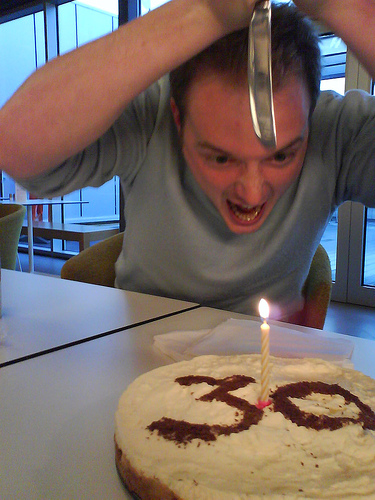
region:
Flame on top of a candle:
[251, 296, 273, 322]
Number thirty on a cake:
[147, 373, 374, 438]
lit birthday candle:
[252, 298, 275, 407]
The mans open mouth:
[225, 202, 270, 227]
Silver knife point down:
[242, 1, 283, 150]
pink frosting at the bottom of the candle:
[255, 397, 272, 410]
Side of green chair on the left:
[0, 192, 25, 269]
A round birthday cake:
[114, 352, 373, 497]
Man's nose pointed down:
[235, 170, 270, 206]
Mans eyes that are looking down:
[197, 135, 316, 167]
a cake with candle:
[91, 266, 371, 479]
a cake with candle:
[124, 270, 356, 486]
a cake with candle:
[146, 265, 353, 499]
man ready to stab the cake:
[78, 1, 365, 491]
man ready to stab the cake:
[106, 5, 373, 481]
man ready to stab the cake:
[119, 2, 362, 472]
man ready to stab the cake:
[115, 7, 368, 470]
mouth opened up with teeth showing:
[215, 192, 269, 226]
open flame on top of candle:
[251, 293, 273, 325]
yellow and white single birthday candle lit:
[254, 297, 275, 404]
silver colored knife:
[241, 0, 286, 155]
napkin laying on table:
[147, 312, 359, 367]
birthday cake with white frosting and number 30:
[107, 295, 374, 498]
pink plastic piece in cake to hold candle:
[250, 396, 276, 413]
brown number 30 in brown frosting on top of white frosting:
[143, 365, 373, 452]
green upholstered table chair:
[58, 223, 337, 330]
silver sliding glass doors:
[300, 15, 374, 314]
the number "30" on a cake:
[118, 298, 373, 498]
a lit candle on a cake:
[138, 286, 366, 498]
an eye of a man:
[200, 148, 236, 167]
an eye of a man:
[266, 151, 294, 167]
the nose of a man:
[233, 168, 274, 210]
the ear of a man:
[165, 95, 185, 142]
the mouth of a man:
[225, 200, 269, 226]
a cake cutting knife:
[244, 0, 279, 151]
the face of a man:
[198, 134, 306, 240]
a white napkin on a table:
[157, 316, 353, 366]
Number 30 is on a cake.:
[115, 354, 373, 499]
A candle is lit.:
[258, 298, 269, 405]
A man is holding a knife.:
[0, 0, 374, 315]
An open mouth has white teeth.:
[227, 197, 272, 222]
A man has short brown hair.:
[172, 9, 320, 142]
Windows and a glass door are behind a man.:
[3, 1, 373, 321]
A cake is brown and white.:
[115, 354, 373, 499]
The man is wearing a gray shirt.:
[20, 74, 374, 318]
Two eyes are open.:
[209, 151, 295, 166]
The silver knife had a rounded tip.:
[247, 0, 277, 151]